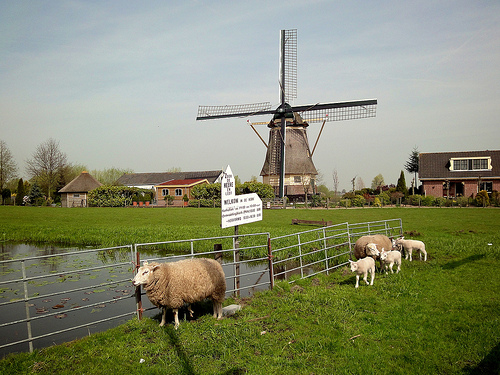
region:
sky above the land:
[81, 28, 195, 86]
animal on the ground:
[125, 245, 245, 343]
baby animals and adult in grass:
[337, 218, 442, 306]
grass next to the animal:
[246, 309, 342, 367]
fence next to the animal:
[55, 233, 130, 321]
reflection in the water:
[21, 230, 62, 261]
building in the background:
[118, 168, 214, 214]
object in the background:
[222, 28, 382, 203]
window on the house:
[468, 177, 497, 198]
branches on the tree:
[26, 137, 86, 198]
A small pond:
[0, 237, 320, 349]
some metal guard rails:
[0, 215, 405, 357]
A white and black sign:
[211, 161, 261, 226]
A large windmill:
[191, 25, 376, 206]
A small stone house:
[415, 150, 495, 200]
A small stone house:
[152, 172, 212, 202]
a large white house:
[111, 165, 222, 190]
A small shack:
[56, 167, 106, 203]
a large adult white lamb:
[125, 255, 230, 320]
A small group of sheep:
[345, 228, 427, 291]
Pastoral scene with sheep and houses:
[15, 40, 492, 362]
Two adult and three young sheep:
[125, 223, 428, 328]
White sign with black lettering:
[217, 161, 264, 228]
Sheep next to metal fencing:
[0, 204, 478, 364]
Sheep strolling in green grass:
[124, 232, 466, 329]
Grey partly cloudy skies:
[13, 2, 495, 151]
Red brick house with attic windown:
[415, 137, 498, 205]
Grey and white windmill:
[198, 26, 384, 206]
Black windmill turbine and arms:
[196, 25, 383, 187]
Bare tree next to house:
[22, 137, 99, 207]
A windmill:
[196, 30, 377, 207]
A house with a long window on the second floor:
[417, 152, 499, 204]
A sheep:
[130, 256, 226, 329]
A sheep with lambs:
[346, 232, 426, 287]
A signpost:
[221, 164, 263, 300]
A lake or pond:
[0, 238, 337, 359]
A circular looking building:
[58, 170, 108, 207]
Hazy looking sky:
[0, 0, 497, 190]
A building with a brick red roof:
[154, 177, 211, 207]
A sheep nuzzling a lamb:
[353, 234, 401, 276]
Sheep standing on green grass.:
[130, 231, 428, 331]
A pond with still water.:
[0, 242, 330, 360]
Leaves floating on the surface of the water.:
[0, 242, 146, 319]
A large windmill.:
[192, 27, 377, 208]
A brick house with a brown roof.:
[418, 152, 498, 202]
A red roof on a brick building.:
[153, 175, 209, 205]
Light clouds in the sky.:
[2, 3, 497, 191]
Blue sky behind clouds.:
[0, 1, 496, 183]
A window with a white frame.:
[448, 152, 490, 172]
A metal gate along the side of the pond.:
[1, 200, 404, 357]